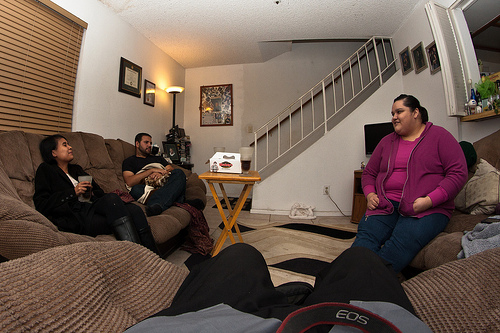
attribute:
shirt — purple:
[368, 120, 462, 205]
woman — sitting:
[321, 64, 454, 279]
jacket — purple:
[372, 132, 467, 185]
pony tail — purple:
[409, 93, 437, 120]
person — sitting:
[41, 133, 138, 233]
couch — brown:
[3, 132, 220, 237]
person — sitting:
[116, 126, 189, 204]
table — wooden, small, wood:
[198, 155, 252, 227]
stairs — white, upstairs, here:
[267, 43, 400, 185]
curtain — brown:
[1, 14, 75, 106]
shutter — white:
[436, 16, 475, 92]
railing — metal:
[256, 41, 355, 133]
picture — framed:
[117, 56, 147, 100]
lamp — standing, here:
[166, 76, 192, 147]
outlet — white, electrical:
[321, 178, 336, 198]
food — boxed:
[206, 157, 238, 171]